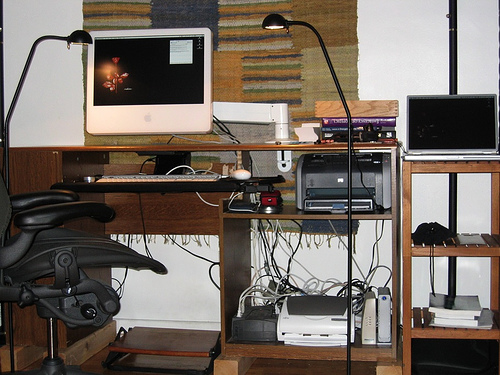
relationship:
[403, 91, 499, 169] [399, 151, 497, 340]
laptop on a shelf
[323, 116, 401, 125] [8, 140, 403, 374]
purple book on a desk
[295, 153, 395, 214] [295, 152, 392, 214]
fax and fax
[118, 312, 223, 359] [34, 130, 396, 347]
foot rest under desk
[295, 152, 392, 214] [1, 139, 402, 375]
fax on desk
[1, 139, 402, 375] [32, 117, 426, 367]
desk in desk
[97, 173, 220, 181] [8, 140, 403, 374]
keyboard on desk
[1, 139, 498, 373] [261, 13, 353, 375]
desk next to blacklamp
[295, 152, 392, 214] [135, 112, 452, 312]
fax on a shelf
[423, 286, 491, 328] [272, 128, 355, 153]
books on a shelf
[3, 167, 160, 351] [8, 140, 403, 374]
chair in front of desk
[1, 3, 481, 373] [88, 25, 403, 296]
room has many electric devices